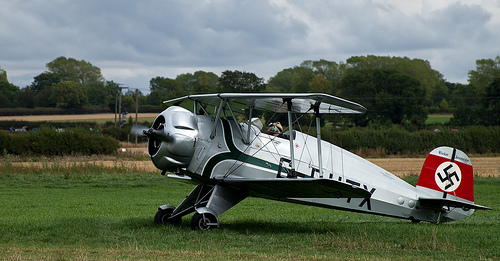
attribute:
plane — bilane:
[171, 93, 460, 230]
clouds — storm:
[4, 7, 99, 78]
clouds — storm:
[82, 7, 189, 89]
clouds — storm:
[129, 7, 229, 83]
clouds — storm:
[206, 7, 341, 72]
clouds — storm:
[339, 5, 489, 79]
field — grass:
[6, 156, 498, 254]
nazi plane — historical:
[124, 74, 490, 247]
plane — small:
[138, 80, 418, 238]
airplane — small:
[149, 77, 481, 232]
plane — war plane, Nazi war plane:
[110, 68, 497, 233]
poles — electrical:
[113, 90, 119, 117]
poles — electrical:
[116, 89, 121, 119]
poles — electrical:
[133, 88, 139, 123]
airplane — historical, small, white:
[144, 92, 492, 229]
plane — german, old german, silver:
[131, 92, 493, 232]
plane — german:
[120, 67, 495, 251]